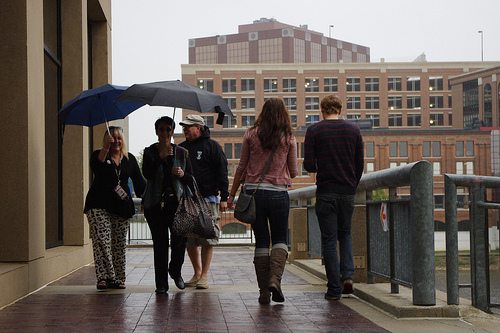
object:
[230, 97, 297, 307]
lady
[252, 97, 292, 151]
hair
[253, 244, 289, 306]
knee high boots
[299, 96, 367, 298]
person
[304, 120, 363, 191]
shirt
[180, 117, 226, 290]
man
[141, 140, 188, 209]
shirt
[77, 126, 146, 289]
lady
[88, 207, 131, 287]
pants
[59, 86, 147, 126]
umbrella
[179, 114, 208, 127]
cap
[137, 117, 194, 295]
lady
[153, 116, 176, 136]
short hair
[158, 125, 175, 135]
glasses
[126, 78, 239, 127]
umbrellas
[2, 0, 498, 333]
scene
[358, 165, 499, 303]
railing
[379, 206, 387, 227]
arrow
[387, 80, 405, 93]
window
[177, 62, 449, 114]
building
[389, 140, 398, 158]
window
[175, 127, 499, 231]
building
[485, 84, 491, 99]
window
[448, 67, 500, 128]
building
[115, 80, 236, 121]
black umbrella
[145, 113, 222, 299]
man and lady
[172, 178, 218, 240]
bag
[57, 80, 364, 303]
people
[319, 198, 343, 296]
leg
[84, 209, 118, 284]
leg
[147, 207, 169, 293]
leg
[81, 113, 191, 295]
two people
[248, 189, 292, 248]
blue jeans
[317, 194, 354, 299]
blue jeans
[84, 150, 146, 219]
black shirt